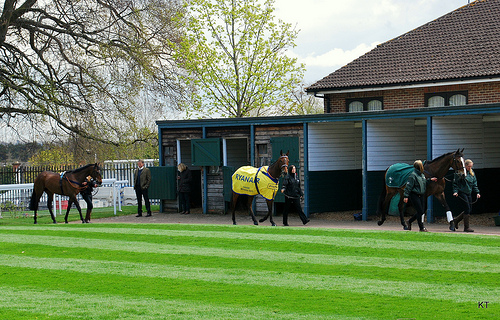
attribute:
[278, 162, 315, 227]
person — short, Skinny 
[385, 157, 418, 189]
cover — green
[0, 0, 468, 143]
sky —  blue,  white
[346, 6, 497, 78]
roof — brown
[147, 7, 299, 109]
tree — green, tall, thin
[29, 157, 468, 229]
horses — brown, big,  tall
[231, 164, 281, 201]
cover — yellow, green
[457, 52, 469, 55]
tile — brown, small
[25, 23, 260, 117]
tree — Tall, Skinny, green, many leaves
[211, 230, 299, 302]
grass — flat, green, short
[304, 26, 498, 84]
roof — brown, tiled, large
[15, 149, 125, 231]
horse — brown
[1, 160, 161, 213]
fence — black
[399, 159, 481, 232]
people — skinny,  thin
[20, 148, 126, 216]
horse — big, tall, brown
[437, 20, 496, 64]
roof — brown, flat, tiled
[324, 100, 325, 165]
wall — Blue,  medium,  wooden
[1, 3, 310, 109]
tree — large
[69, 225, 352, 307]
grass — green, flat, short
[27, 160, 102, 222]
horse — tall, brown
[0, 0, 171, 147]
tree — large, bare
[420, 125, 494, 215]
dividers — green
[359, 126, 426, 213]
dividers — green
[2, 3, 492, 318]
picture —  large,  open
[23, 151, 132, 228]
horse — brown, tall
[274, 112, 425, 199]
stables — small, blue, narrow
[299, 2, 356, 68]
clouds — overcast